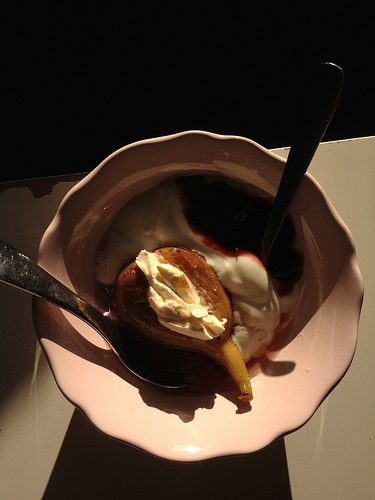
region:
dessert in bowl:
[30, 122, 369, 485]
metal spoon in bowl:
[0, 229, 199, 412]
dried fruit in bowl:
[102, 233, 257, 413]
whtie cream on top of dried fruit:
[126, 249, 227, 342]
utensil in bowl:
[260, 47, 347, 245]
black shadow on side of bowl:
[250, 354, 313, 380]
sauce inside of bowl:
[171, 167, 310, 311]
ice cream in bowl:
[88, 192, 292, 372]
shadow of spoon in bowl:
[33, 294, 218, 433]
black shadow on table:
[17, 391, 310, 497]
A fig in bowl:
[113, 244, 256, 402]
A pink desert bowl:
[30, 129, 365, 464]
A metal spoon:
[0, 239, 197, 389]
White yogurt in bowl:
[93, 176, 300, 366]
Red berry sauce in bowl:
[171, 172, 300, 292]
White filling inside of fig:
[133, 248, 227, 342]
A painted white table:
[0, 135, 374, 498]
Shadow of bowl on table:
[39, 404, 292, 498]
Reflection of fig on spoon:
[75, 299, 122, 344]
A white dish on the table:
[29, 121, 365, 464]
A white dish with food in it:
[24, 132, 364, 462]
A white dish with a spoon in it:
[4, 116, 359, 462]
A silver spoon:
[0, 239, 189, 400]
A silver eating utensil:
[1, 238, 198, 394]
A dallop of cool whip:
[136, 249, 227, 335]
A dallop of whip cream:
[135, 249, 229, 342]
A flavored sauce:
[180, 170, 316, 292]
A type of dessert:
[94, 181, 307, 399]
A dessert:
[98, 192, 312, 404]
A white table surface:
[303, 424, 370, 477]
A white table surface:
[5, 416, 48, 497]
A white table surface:
[328, 149, 373, 190]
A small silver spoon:
[2, 261, 186, 401]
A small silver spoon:
[257, 111, 325, 274]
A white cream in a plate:
[233, 261, 272, 361]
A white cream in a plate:
[118, 205, 173, 251]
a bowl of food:
[18, 102, 369, 429]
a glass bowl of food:
[25, 159, 331, 377]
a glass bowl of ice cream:
[46, 162, 373, 474]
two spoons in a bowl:
[17, 154, 369, 395]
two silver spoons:
[12, 159, 358, 328]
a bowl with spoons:
[11, 163, 356, 443]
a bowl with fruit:
[72, 180, 368, 366]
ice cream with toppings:
[70, 156, 367, 445]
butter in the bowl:
[120, 245, 226, 353]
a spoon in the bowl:
[256, 77, 329, 299]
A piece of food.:
[125, 250, 226, 336]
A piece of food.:
[215, 252, 268, 291]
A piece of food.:
[225, 303, 274, 340]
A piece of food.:
[225, 330, 262, 358]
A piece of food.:
[80, 185, 203, 261]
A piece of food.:
[134, 252, 174, 305]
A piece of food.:
[141, 289, 198, 321]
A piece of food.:
[183, 305, 204, 323]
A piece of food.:
[160, 318, 211, 341]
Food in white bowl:
[96, 209, 307, 382]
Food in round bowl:
[101, 194, 291, 366]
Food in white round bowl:
[106, 193, 316, 370]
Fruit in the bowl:
[119, 238, 269, 400]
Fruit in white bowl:
[100, 238, 264, 403]